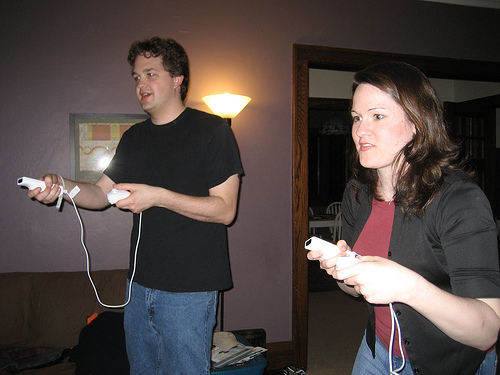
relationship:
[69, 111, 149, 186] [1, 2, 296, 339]
picture on a wall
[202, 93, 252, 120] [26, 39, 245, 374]
light behind man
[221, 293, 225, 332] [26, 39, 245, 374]
pole behind man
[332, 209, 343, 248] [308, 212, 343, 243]
chair at a table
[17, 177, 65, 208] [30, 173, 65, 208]
wiimote in man's right hand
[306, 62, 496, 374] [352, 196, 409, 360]
woman wearing a shirt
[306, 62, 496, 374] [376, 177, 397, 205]
woman wearing a necklace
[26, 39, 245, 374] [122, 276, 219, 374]
man wearing jeans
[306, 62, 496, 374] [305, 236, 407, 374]
woman holding controller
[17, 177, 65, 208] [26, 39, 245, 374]
wiimote held by man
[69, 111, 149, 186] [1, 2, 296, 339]
picture hanging on wall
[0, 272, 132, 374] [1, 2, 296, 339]
couch against wall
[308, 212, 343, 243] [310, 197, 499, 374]
table in other room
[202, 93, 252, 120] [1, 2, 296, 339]
light on wall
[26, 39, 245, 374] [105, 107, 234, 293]
man wearing a tshirt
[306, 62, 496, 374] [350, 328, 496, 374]
woman wearing jean pants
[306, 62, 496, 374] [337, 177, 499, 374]
woman wearing a jacket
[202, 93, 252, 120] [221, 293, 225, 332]
light has a pole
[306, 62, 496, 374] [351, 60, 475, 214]
woman has brown hair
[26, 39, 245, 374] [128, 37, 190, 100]
man has brown hair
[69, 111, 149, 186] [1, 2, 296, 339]
picture on wall